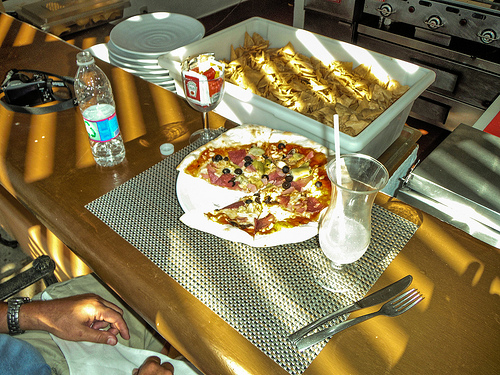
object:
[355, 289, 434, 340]
fork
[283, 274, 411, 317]
knife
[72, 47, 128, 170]
bottle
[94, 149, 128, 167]
water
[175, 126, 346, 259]
pizza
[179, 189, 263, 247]
slice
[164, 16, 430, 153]
box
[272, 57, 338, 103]
chips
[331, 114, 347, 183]
straw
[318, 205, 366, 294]
glass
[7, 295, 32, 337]
watch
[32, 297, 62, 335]
write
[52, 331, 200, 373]
napkin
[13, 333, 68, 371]
lap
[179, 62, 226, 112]
sauce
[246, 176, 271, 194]
ham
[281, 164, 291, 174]
olive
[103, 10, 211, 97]
stack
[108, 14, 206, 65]
plates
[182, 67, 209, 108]
packets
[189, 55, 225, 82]
condiments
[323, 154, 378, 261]
tiki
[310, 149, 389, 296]
cup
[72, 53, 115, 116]
plastic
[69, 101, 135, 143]
lable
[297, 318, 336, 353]
silver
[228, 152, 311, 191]
toppings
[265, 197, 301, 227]
cheese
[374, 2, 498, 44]
dials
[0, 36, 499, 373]
table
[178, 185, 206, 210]
white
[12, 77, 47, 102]
black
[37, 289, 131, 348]
hand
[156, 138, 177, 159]
lid